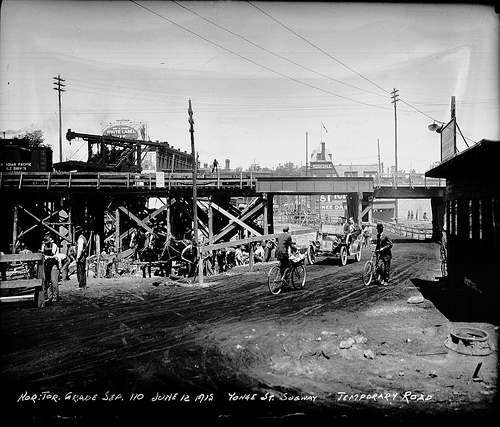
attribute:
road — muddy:
[5, 218, 497, 423]